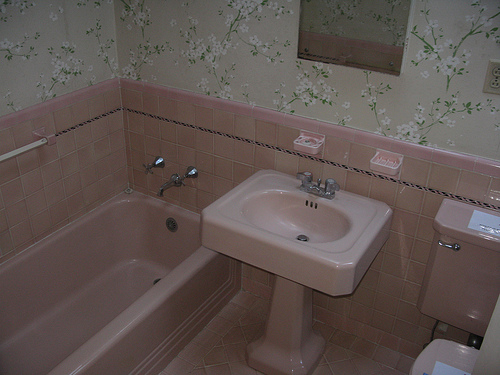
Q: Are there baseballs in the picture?
A: No, there are no baseballs.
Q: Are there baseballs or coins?
A: No, there are no baseballs or coins.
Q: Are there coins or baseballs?
A: No, there are no baseballs or coins.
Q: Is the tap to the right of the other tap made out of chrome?
A: Yes, the tap is made of chrome.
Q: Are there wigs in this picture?
A: No, there are no wigs.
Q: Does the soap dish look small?
A: Yes, the soap dish is small.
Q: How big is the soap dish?
A: The soap dish is small.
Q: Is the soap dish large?
A: No, the soap dish is small.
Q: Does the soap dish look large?
A: No, the soap dish is small.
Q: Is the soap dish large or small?
A: The soap dish is small.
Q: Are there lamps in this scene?
A: No, there are no lamps.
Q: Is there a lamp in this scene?
A: No, there are no lamps.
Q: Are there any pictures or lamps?
A: No, there are no lamps or pictures.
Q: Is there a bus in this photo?
A: No, there are no buses.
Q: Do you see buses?
A: No, there are no buses.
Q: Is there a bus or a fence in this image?
A: No, there are no buses or fences.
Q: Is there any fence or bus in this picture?
A: No, there are no buses or fences.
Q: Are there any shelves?
A: No, there are no shelves.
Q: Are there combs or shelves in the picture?
A: No, there are no shelves or combs.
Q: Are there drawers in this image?
A: No, there are no drawers.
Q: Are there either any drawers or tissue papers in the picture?
A: No, there are no drawers or tissue papers.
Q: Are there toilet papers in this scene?
A: No, there are no toilet papers.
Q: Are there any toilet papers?
A: No, there are no toilet papers.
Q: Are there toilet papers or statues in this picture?
A: No, there are no toilet papers or statues.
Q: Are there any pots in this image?
A: No, there are no pots.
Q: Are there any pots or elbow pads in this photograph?
A: No, there are no pots or elbow pads.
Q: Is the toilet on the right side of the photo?
A: Yes, the toilet is on the right of the image.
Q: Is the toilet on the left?
A: No, the toilet is on the right of the image.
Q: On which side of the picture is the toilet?
A: The toilet is on the right of the image.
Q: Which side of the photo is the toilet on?
A: The toilet is on the right of the image.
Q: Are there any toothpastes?
A: No, there are no toothpastes.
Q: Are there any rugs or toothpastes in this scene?
A: No, there are no toothpastes or rugs.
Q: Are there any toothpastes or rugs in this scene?
A: No, there are no toothpastes or rugs.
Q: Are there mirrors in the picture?
A: Yes, there is a mirror.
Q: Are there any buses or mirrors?
A: Yes, there is a mirror.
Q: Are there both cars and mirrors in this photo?
A: No, there is a mirror but no cars.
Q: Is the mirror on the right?
A: Yes, the mirror is on the right of the image.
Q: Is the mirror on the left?
A: No, the mirror is on the right of the image.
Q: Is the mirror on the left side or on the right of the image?
A: The mirror is on the right of the image.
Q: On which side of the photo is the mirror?
A: The mirror is on the right of the image.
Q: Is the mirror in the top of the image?
A: Yes, the mirror is in the top of the image.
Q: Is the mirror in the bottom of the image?
A: No, the mirror is in the top of the image.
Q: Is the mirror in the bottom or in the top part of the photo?
A: The mirror is in the top of the image.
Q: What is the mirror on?
A: The mirror is on the wall.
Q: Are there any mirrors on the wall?
A: Yes, there is a mirror on the wall.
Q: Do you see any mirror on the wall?
A: Yes, there is a mirror on the wall.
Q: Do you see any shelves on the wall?
A: No, there is a mirror on the wall.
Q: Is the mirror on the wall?
A: Yes, the mirror is on the wall.